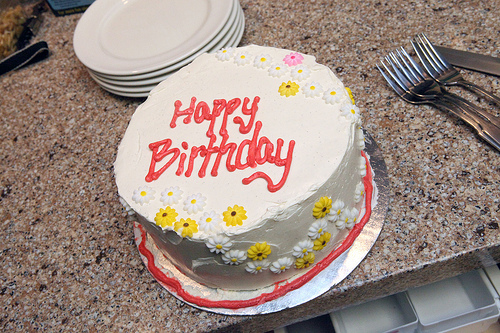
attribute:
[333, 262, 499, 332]
storage containers — white 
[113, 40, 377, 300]
white birthday cake — white 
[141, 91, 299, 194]
red lettering — red 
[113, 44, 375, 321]
candy decorations — daisy 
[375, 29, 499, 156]
silver forks — silver 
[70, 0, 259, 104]
five white plates — white 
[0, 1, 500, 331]
beige granite — beige 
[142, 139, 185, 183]
red icing b — red 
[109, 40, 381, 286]
"pink candy daisy — pink 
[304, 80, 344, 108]
two white daisy — white 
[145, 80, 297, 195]
letters in red — red 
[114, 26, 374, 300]
flowers on cake — white , yellow 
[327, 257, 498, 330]
open drawer — open 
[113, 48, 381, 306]
uncut birthday cake — white 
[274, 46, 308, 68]
flower on cake — pink 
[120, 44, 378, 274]
colored flowers — different 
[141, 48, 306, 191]
on a birthday cake — happy birthday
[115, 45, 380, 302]
frosting on a — white 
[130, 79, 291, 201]
frosting — Happy Birthday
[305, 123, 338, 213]
frosting — white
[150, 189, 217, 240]
flower — decorations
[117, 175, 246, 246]
candy — yellow , white 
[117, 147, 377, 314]
frosting — red 